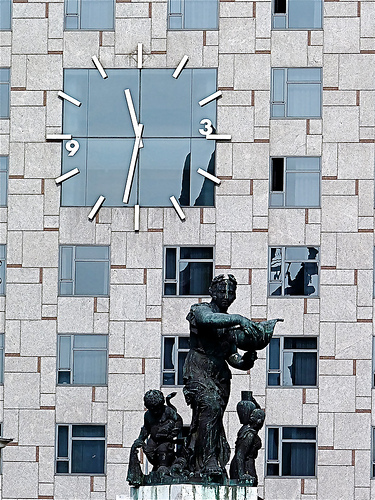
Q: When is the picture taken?
A: 11:32.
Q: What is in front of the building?
A: Statue.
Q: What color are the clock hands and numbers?
A: White.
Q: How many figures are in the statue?
A: Three.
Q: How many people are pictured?
A: None.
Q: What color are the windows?
A: Blue.